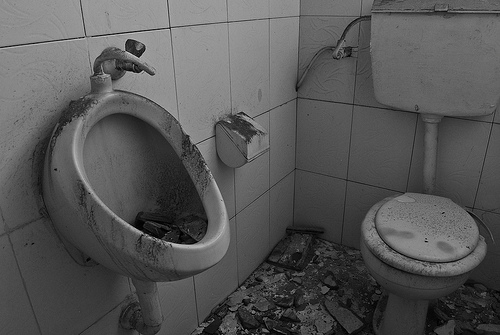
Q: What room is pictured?
A: It is a bathroom.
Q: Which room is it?
A: It is a bathroom.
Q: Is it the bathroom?
A: Yes, it is the bathroom.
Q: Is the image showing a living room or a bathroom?
A: It is showing a bathroom.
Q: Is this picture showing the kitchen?
A: No, the picture is showing the bathroom.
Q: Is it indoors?
A: Yes, it is indoors.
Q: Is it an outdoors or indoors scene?
A: It is indoors.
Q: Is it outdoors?
A: No, it is indoors.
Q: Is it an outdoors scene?
A: No, it is indoors.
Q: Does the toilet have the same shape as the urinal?
A: Yes, both the toilet and the urinal are round.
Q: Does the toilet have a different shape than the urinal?
A: No, both the toilet and the urinal are round.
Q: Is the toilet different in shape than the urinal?
A: No, both the toilet and the urinal are round.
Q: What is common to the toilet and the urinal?
A: The shape, both the toilet and the urinal are round.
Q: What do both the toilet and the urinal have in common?
A: The shape, both the toilet and the urinal are round.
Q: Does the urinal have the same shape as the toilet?
A: Yes, both the urinal and the toilet are round.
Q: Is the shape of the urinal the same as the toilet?
A: Yes, both the urinal and the toilet are round.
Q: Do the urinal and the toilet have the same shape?
A: Yes, both the urinal and the toilet are round.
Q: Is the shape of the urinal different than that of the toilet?
A: No, both the urinal and the toilet are round.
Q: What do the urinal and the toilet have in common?
A: The shape, both the urinal and the toilet are round.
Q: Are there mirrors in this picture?
A: No, there are no mirrors.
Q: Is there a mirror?
A: No, there are no mirrors.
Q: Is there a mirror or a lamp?
A: No, there are no mirrors or lamps.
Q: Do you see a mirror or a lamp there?
A: No, there are no mirrors or lamps.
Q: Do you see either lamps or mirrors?
A: No, there are no mirrors or lamps.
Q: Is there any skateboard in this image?
A: No, there are no skateboards.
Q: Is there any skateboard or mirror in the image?
A: No, there are no skateboards or mirrors.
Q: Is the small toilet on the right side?
A: Yes, the toilet is on the right of the image.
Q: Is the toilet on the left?
A: No, the toilet is on the right of the image.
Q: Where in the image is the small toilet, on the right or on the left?
A: The toilet is on the right of the image.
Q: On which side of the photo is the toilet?
A: The toilet is on the right of the image.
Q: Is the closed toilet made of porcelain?
A: Yes, the toilet is made of porcelain.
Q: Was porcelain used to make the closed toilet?
A: Yes, the toilet is made of porcelain.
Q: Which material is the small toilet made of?
A: The toilet is made of porcelain.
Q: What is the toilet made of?
A: The toilet is made of porcelain.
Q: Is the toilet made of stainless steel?
A: No, the toilet is made of porcelain.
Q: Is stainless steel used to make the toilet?
A: No, the toilet is made of porcelain.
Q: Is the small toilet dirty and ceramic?
A: Yes, the toilet is dirty and ceramic.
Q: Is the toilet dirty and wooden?
A: No, the toilet is dirty but ceramic.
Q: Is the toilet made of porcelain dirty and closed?
A: Yes, the toilet is dirty and closed.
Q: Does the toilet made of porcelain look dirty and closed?
A: Yes, the toilet is dirty and closed.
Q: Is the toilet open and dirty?
A: No, the toilet is dirty but closed.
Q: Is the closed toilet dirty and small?
A: Yes, the toilet is dirty and small.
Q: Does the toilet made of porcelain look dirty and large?
A: No, the toilet is dirty but small.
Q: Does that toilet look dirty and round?
A: Yes, the toilet is dirty and round.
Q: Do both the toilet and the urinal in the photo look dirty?
A: Yes, both the toilet and the urinal are dirty.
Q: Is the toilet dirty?
A: Yes, the toilet is dirty.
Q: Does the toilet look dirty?
A: Yes, the toilet is dirty.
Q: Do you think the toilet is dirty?
A: Yes, the toilet is dirty.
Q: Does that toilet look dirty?
A: Yes, the toilet is dirty.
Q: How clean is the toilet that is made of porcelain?
A: The toilet is dirty.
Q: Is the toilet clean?
A: No, the toilet is dirty.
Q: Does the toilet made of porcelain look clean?
A: No, the toilet is dirty.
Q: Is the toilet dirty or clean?
A: The toilet is dirty.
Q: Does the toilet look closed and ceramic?
A: Yes, the toilet is closed and ceramic.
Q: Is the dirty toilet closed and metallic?
A: No, the toilet is closed but ceramic.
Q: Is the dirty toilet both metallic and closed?
A: No, the toilet is closed but ceramic.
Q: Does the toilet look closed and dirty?
A: Yes, the toilet is closed and dirty.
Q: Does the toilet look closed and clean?
A: No, the toilet is closed but dirty.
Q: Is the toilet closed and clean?
A: No, the toilet is closed but dirty.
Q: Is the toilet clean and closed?
A: No, the toilet is closed but dirty.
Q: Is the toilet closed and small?
A: Yes, the toilet is closed and small.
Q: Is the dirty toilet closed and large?
A: No, the toilet is closed but small.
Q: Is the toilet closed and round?
A: Yes, the toilet is closed and round.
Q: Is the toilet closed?
A: Yes, the toilet is closed.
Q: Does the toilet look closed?
A: Yes, the toilet is closed.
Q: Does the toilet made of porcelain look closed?
A: Yes, the toilet is closed.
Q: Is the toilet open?
A: No, the toilet is closed.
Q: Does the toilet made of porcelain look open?
A: No, the toilet is closed.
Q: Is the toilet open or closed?
A: The toilet is closed.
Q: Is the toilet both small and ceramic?
A: Yes, the toilet is small and ceramic.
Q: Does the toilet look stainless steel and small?
A: No, the toilet is small but ceramic.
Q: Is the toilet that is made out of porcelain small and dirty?
A: Yes, the toilet is small and dirty.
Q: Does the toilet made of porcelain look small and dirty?
A: Yes, the toilet is small and dirty.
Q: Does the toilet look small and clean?
A: No, the toilet is small but dirty.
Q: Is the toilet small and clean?
A: No, the toilet is small but dirty.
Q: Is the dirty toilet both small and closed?
A: Yes, the toilet is small and closed.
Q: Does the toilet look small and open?
A: No, the toilet is small but closed.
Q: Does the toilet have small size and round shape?
A: Yes, the toilet is small and round.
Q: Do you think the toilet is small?
A: Yes, the toilet is small.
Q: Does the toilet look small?
A: Yes, the toilet is small.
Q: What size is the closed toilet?
A: The toilet is small.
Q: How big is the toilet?
A: The toilet is small.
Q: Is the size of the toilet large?
A: No, the toilet is small.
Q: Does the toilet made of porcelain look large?
A: No, the toilet is small.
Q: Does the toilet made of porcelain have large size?
A: No, the toilet is small.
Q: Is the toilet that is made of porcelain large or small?
A: The toilet is small.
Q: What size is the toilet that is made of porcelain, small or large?
A: The toilet is small.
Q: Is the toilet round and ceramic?
A: Yes, the toilet is round and ceramic.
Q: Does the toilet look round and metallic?
A: No, the toilet is round but ceramic.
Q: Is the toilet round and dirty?
A: Yes, the toilet is round and dirty.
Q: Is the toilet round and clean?
A: No, the toilet is round but dirty.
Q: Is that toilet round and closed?
A: Yes, the toilet is round and closed.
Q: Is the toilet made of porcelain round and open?
A: No, the toilet is round but closed.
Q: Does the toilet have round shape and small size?
A: Yes, the toilet is round and small.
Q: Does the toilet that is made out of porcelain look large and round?
A: No, the toilet is round but small.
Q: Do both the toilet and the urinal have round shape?
A: Yes, both the toilet and the urinal are round.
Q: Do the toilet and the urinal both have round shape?
A: Yes, both the toilet and the urinal are round.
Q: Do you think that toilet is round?
A: Yes, the toilet is round.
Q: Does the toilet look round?
A: Yes, the toilet is round.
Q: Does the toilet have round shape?
A: Yes, the toilet is round.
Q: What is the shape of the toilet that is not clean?
A: The toilet is round.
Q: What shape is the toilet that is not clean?
A: The toilet is round.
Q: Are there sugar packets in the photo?
A: No, there are no sugar packets.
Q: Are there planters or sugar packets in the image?
A: No, there are no sugar packets or planters.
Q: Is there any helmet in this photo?
A: No, there are no helmets.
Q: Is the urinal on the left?
A: Yes, the urinal is on the left of the image.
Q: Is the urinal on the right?
A: No, the urinal is on the left of the image.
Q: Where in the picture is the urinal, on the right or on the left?
A: The urinal is on the left of the image.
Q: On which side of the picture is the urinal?
A: The urinal is on the left of the image.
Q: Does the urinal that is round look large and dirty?
A: Yes, the urinal is large and dirty.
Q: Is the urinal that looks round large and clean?
A: No, the urinal is large but dirty.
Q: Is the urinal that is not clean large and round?
A: Yes, the urinal is large and round.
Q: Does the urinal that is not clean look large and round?
A: Yes, the urinal is large and round.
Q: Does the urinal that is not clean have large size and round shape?
A: Yes, the urinal is large and round.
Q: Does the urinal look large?
A: Yes, the urinal is large.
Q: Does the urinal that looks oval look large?
A: Yes, the urinal is large.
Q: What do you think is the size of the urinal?
A: The urinal is large.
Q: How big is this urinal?
A: The urinal is large.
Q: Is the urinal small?
A: No, the urinal is large.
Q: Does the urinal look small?
A: No, the urinal is large.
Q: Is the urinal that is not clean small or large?
A: The urinal is large.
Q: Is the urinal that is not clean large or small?
A: The urinal is large.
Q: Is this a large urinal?
A: Yes, this is a large urinal.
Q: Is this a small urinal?
A: No, this is a large urinal.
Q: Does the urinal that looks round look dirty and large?
A: Yes, the urinal is dirty and large.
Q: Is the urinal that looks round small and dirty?
A: No, the urinal is dirty but large.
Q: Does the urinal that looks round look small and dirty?
A: No, the urinal is dirty but large.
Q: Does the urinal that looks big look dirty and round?
A: Yes, the urinal is dirty and round.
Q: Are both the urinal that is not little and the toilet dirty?
A: Yes, both the urinal and the toilet are dirty.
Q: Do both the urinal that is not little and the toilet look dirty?
A: Yes, both the urinal and the toilet are dirty.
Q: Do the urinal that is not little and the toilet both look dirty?
A: Yes, both the urinal and the toilet are dirty.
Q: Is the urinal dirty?
A: Yes, the urinal is dirty.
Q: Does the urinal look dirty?
A: Yes, the urinal is dirty.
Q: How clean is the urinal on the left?
A: The urinal is dirty.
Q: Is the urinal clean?
A: No, the urinal is dirty.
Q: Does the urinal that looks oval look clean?
A: No, the urinal is dirty.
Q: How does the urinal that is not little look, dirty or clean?
A: The urinal is dirty.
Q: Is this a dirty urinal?
A: Yes, this is a dirty urinal.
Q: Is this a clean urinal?
A: No, this is a dirty urinal.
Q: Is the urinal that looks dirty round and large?
A: Yes, the urinal is round and large.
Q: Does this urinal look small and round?
A: No, the urinal is round but large.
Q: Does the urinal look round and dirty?
A: Yes, the urinal is round and dirty.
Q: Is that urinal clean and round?
A: No, the urinal is round but dirty.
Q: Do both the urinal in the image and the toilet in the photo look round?
A: Yes, both the urinal and the toilet are round.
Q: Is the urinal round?
A: Yes, the urinal is round.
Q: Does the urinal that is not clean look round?
A: Yes, the urinal is round.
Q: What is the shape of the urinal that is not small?
A: The urinal is round.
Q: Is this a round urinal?
A: Yes, this is a round urinal.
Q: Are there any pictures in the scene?
A: No, there are no pictures.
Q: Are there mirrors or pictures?
A: No, there are no pictures or mirrors.